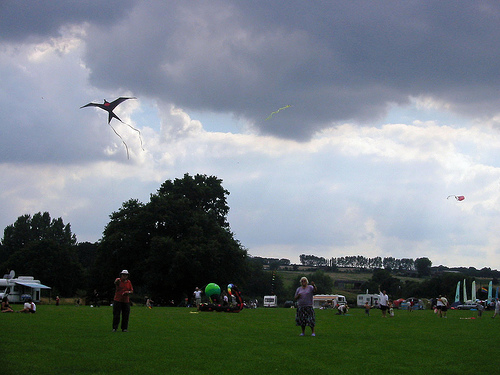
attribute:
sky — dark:
[19, 25, 494, 275]